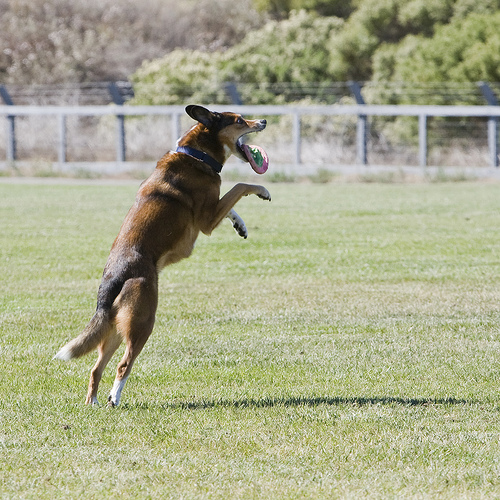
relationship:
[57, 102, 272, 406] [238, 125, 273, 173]
dog catching with h mouth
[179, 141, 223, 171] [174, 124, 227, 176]
collar on neck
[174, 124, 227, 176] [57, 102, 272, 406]
neck of dog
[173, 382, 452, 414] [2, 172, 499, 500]
shadow on grass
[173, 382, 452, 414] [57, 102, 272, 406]
shadow of dog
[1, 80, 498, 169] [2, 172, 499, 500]
fence on grass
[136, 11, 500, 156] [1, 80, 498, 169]
trees behind fence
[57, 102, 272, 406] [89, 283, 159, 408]
dog standing on hind legs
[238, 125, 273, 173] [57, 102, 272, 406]
mouth of dog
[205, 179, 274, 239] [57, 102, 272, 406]
front legs of dog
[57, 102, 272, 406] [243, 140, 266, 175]
dog catching frisbee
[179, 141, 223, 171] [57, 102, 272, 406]
collar on dog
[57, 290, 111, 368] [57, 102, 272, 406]
tail on dog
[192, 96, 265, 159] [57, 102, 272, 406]
head of dog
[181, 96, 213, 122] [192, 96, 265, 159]
ears on head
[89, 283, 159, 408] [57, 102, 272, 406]
hind legs of dog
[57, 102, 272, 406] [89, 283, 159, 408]
dog standing on h hind legs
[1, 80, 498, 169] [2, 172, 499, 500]
fence around grass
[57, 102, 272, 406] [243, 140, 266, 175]
dog catching a frisbee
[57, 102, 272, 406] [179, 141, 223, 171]
dog wearing a collar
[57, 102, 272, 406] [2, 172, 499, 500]
dog playing on grass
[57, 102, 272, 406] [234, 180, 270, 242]
dog has paws